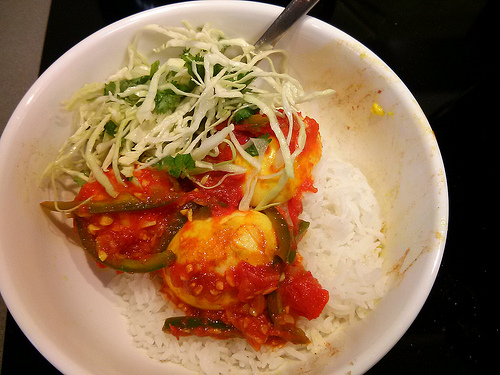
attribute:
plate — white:
[306, 37, 494, 365]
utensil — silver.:
[193, 0, 333, 77]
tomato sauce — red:
[283, 274, 323, 309]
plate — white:
[0, 0, 449, 373]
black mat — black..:
[436, 10, 498, 366]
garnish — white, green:
[40, 18, 337, 209]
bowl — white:
[0, 2, 452, 374]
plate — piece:
[405, 78, 448, 238]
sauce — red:
[80, 112, 326, 346]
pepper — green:
[137, 251, 166, 269]